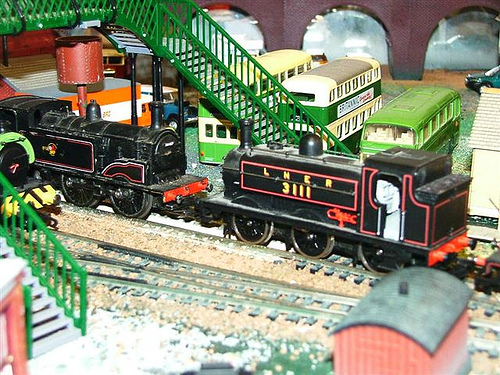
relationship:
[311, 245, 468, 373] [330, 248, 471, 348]
building with curved roof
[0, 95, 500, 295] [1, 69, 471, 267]
train in train set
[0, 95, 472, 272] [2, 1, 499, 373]
train in train set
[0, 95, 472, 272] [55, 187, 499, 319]
train on track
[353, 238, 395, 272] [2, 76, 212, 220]
wheel on train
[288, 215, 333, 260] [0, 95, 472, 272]
wheel on train